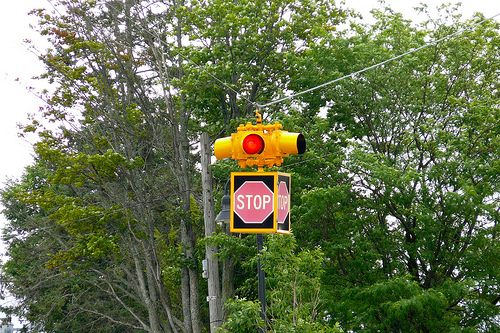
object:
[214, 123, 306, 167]
signal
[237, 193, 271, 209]
stop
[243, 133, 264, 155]
light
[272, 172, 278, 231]
border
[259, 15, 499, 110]
cable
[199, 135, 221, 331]
tree trunk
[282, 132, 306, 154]
shield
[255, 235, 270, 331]
post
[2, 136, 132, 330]
trees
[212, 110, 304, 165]
framework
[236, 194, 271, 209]
word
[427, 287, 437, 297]
leaves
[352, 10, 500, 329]
tree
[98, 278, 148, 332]
branches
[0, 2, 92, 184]
sky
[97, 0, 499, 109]
rope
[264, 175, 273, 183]
blackness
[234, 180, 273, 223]
sign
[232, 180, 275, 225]
background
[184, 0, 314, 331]
tree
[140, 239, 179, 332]
branches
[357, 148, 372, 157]
leaves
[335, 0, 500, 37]
sky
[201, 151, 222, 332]
pole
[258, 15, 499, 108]
power line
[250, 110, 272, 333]
bracket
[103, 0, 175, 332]
green trees